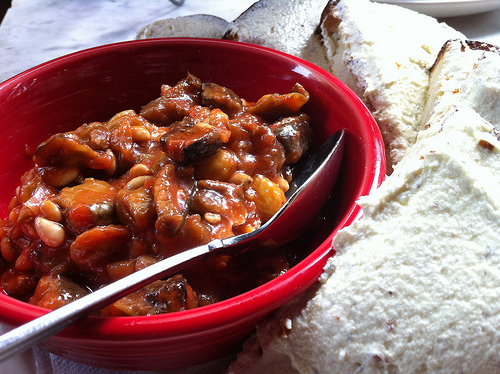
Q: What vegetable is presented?
A: The vegetable is chili.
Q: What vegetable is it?
A: The vegetable is chili.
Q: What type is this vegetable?
A: This is chili.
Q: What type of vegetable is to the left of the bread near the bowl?
A: The vegetable is chili.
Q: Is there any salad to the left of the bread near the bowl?
A: No, there is chili to the left of the bread.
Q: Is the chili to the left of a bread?
A: Yes, the chili is to the left of a bread.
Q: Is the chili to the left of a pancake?
A: No, the chili is to the left of a bread.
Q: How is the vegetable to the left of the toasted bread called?
A: The vegetable is chili.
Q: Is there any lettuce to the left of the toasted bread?
A: No, there is chili to the left of the bread.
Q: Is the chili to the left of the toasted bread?
A: Yes, the chili is to the left of the bread.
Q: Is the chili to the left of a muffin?
A: No, the chili is to the left of the bread.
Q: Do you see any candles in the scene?
A: No, there are no candles.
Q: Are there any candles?
A: No, there are no candles.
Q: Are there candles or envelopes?
A: No, there are no candles or envelopes.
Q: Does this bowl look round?
A: Yes, the bowl is round.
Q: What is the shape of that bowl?
A: The bowl is round.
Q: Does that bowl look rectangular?
A: No, the bowl is round.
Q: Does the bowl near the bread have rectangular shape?
A: No, the bowl is round.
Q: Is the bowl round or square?
A: The bowl is round.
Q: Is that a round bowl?
A: Yes, that is a round bowl.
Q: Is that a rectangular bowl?
A: No, that is a round bowl.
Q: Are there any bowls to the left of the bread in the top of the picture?
A: Yes, there is a bowl to the left of the bread.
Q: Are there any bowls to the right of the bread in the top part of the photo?
A: No, the bowl is to the left of the bread.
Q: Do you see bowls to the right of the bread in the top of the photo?
A: No, the bowl is to the left of the bread.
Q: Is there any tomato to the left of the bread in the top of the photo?
A: No, there is a bowl to the left of the bread.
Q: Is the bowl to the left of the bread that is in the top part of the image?
A: Yes, the bowl is to the left of the bread.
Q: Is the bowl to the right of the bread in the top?
A: No, the bowl is to the left of the bread.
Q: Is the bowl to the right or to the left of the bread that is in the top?
A: The bowl is to the left of the bread.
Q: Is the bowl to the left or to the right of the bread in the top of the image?
A: The bowl is to the left of the bread.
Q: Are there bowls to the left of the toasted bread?
A: Yes, there is a bowl to the left of the bread.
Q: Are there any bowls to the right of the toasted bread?
A: No, the bowl is to the left of the bread.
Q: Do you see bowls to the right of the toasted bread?
A: No, the bowl is to the left of the bread.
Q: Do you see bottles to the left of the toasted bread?
A: No, there is a bowl to the left of the bread.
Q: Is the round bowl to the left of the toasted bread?
A: Yes, the bowl is to the left of the bread.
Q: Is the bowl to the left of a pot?
A: No, the bowl is to the left of the bread.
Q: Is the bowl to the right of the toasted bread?
A: No, the bowl is to the left of the bread.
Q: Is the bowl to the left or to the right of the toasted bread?
A: The bowl is to the left of the bread.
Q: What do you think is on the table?
A: The bowl is on the table.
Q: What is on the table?
A: The bowl is on the table.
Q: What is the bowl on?
A: The bowl is on the table.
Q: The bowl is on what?
A: The bowl is on the table.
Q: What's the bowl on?
A: The bowl is on the table.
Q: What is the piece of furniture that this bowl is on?
A: The piece of furniture is a table.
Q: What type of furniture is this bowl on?
A: The bowl is on the table.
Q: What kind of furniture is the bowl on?
A: The bowl is on the table.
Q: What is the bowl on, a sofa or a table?
A: The bowl is on a table.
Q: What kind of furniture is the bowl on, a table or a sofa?
A: The bowl is on a table.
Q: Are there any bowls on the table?
A: Yes, there is a bowl on the table.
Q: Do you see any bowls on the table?
A: Yes, there is a bowl on the table.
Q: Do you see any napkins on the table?
A: No, there is a bowl on the table.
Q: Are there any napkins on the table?
A: No, there is a bowl on the table.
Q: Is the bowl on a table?
A: Yes, the bowl is on a table.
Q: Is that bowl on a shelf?
A: No, the bowl is on a table.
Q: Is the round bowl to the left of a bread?
A: Yes, the bowl is to the left of a bread.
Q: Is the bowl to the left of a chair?
A: No, the bowl is to the left of a bread.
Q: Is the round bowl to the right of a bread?
A: No, the bowl is to the left of a bread.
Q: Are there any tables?
A: Yes, there is a table.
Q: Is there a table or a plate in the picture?
A: Yes, there is a table.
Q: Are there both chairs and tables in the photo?
A: No, there is a table but no chairs.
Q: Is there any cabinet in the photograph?
A: No, there are no cabinets.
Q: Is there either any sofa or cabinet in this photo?
A: No, there are no cabinets or sofas.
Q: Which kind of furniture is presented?
A: The furniture is a table.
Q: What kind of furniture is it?
A: The piece of furniture is a table.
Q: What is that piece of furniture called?
A: This is a table.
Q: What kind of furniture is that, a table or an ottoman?
A: This is a table.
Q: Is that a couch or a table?
A: That is a table.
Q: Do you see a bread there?
A: Yes, there is a bread.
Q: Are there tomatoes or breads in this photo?
A: Yes, there is a bread.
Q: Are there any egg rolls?
A: No, there are no egg rolls.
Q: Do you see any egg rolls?
A: No, there are no egg rolls.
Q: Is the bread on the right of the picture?
A: Yes, the bread is on the right of the image.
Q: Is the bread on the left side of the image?
A: No, the bread is on the right of the image.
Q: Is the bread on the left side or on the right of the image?
A: The bread is on the right of the image.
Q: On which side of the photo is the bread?
A: The bread is on the right of the image.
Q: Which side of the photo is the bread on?
A: The bread is on the right of the image.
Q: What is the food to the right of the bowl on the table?
A: The food is a bread.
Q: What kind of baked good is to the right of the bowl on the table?
A: The food is a bread.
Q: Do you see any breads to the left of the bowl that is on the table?
A: No, the bread is to the right of the bowl.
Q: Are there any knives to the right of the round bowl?
A: No, there is a bread to the right of the bowl.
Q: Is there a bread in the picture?
A: Yes, there is a bread.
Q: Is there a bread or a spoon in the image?
A: Yes, there is a bread.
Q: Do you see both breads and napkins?
A: No, there is a bread but no napkins.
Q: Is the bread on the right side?
A: Yes, the bread is on the right of the image.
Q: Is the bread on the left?
A: No, the bread is on the right of the image.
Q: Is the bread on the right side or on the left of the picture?
A: The bread is on the right of the image.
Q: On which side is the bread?
A: The bread is on the right of the image.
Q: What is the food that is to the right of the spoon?
A: The food is a bread.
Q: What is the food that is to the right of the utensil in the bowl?
A: The food is a bread.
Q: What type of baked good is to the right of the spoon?
A: The food is a bread.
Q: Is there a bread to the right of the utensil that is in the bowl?
A: Yes, there is a bread to the right of the spoon.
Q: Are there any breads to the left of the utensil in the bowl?
A: No, the bread is to the right of the spoon.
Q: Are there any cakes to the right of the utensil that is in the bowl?
A: No, there is a bread to the right of the spoon.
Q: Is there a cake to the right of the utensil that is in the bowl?
A: No, there is a bread to the right of the spoon.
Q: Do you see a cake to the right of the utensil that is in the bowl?
A: No, there is a bread to the right of the spoon.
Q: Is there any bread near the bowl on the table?
A: Yes, there is a bread near the bowl.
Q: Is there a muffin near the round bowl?
A: No, there is a bread near the bowl.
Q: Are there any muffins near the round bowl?
A: No, there is a bread near the bowl.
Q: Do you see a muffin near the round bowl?
A: No, there is a bread near the bowl.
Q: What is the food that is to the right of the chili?
A: The food is a bread.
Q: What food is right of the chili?
A: The food is a bread.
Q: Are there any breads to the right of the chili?
A: Yes, there is a bread to the right of the chili.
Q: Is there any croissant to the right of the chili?
A: No, there is a bread to the right of the chili.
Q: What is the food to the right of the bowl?
A: The food is a bread.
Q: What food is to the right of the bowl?
A: The food is a bread.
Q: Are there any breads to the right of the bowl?
A: Yes, there is a bread to the right of the bowl.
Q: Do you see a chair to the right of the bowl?
A: No, there is a bread to the right of the bowl.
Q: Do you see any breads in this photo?
A: Yes, there is a bread.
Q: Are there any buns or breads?
A: Yes, there is a bread.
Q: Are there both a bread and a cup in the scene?
A: No, there is a bread but no cups.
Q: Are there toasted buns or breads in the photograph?
A: Yes, there is a toasted bread.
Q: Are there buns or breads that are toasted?
A: Yes, the bread is toasted.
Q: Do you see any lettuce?
A: No, there is no lettuce.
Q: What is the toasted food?
A: The food is a bread.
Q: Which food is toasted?
A: The food is a bread.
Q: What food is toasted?
A: The food is a bread.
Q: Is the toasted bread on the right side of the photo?
A: Yes, the bread is on the right of the image.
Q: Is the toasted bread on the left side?
A: No, the bread is on the right of the image.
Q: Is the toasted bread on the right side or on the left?
A: The bread is on the right of the image.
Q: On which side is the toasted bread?
A: The bread is on the right of the image.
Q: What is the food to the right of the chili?
A: The food is a bread.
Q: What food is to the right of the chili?
A: The food is a bread.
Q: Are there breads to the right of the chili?
A: Yes, there is a bread to the right of the chili.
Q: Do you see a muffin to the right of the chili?
A: No, there is a bread to the right of the chili.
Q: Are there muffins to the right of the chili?
A: No, there is a bread to the right of the chili.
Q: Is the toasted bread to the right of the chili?
A: Yes, the bread is to the right of the chili.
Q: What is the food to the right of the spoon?
A: The food is a bread.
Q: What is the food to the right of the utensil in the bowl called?
A: The food is a bread.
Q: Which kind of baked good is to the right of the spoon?
A: The food is a bread.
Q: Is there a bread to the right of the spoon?
A: Yes, there is a bread to the right of the spoon.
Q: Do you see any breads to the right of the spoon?
A: Yes, there is a bread to the right of the spoon.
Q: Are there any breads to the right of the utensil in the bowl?
A: Yes, there is a bread to the right of the spoon.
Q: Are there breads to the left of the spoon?
A: No, the bread is to the right of the spoon.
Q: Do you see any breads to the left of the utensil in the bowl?
A: No, the bread is to the right of the spoon.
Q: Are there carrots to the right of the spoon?
A: No, there is a bread to the right of the spoon.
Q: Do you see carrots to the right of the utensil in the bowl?
A: No, there is a bread to the right of the spoon.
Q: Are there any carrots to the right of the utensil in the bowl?
A: No, there is a bread to the right of the spoon.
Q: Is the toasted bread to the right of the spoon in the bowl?
A: Yes, the bread is to the right of the spoon.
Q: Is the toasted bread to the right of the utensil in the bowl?
A: Yes, the bread is to the right of the spoon.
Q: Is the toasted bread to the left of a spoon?
A: No, the bread is to the right of a spoon.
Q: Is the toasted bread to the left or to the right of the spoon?
A: The bread is to the right of the spoon.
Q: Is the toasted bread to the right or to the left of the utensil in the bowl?
A: The bread is to the right of the spoon.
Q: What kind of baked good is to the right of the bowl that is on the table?
A: The food is a bread.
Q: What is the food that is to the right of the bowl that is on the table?
A: The food is a bread.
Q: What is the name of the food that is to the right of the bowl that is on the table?
A: The food is a bread.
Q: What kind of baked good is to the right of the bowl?
A: The food is a bread.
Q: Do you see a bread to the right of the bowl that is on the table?
A: Yes, there is a bread to the right of the bowl.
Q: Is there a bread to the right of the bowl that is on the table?
A: Yes, there is a bread to the right of the bowl.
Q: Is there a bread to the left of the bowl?
A: No, the bread is to the right of the bowl.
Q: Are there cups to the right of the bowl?
A: No, there is a bread to the right of the bowl.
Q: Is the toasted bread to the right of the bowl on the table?
A: Yes, the bread is to the right of the bowl.